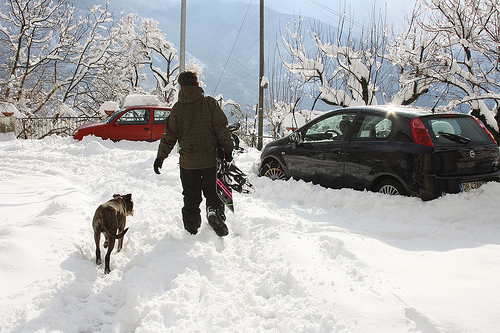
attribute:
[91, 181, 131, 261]
dog — brown, walking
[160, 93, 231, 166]
jacket — brown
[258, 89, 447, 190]
car — black, parked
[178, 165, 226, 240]
pants — black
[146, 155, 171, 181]
glove — black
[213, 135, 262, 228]
snowboard — black